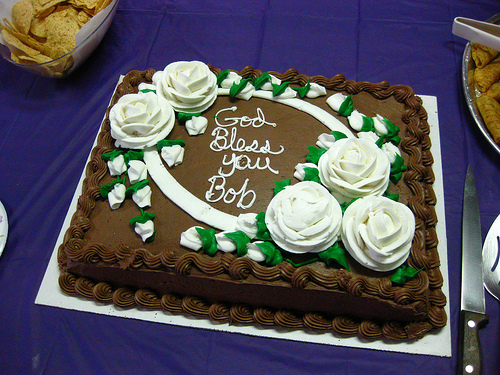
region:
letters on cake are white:
[196, 90, 286, 237]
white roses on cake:
[115, 50, 411, 342]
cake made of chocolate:
[76, 47, 430, 341]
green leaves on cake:
[101, 140, 389, 286]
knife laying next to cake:
[448, 158, 489, 371]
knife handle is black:
[444, 301, 494, 367]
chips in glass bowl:
[3, 0, 103, 70]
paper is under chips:
[1, 2, 101, 56]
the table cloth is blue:
[1, 0, 491, 359]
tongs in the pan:
[444, 8, 499, 58]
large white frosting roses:
[257, 129, 414, 279]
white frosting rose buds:
[99, 141, 282, 262]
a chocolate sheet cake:
[50, 54, 465, 341]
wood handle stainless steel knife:
[453, 148, 485, 374]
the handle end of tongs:
[448, 7, 498, 54]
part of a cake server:
[478, 171, 498, 359]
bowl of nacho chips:
[1, 6, 111, 82]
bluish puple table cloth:
[4, 69, 76, 372]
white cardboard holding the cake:
[28, 269, 295, 361]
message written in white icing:
[191, 99, 292, 214]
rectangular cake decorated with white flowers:
[55, 41, 457, 349]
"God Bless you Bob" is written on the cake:
[191, 95, 293, 216]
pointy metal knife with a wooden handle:
[449, 142, 499, 371]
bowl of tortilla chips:
[6, 5, 119, 71]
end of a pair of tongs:
[442, 6, 498, 63]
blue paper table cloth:
[166, 4, 427, 67]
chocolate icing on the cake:
[51, 220, 194, 342]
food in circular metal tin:
[449, 15, 499, 164]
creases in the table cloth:
[138, 0, 429, 68]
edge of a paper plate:
[1, 140, 16, 312]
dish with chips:
[0, 0, 115, 73]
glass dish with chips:
[0, 0, 117, 77]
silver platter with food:
[452, 11, 498, 153]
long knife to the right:
[458, 165, 487, 368]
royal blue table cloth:
[2, 0, 497, 373]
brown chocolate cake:
[57, 60, 446, 345]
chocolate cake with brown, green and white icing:
[55, 59, 448, 346]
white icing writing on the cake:
[205, 105, 283, 208]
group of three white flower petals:
[265, 133, 407, 269]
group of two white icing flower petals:
[105, 59, 221, 146]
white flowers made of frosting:
[251, 107, 448, 304]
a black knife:
[428, 142, 494, 372]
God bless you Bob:
[173, 76, 296, 227]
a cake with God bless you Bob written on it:
[96, 65, 452, 355]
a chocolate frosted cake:
[77, 70, 466, 342]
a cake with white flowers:
[76, 61, 451, 338]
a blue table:
[18, 85, 476, 368]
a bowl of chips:
[1, 1, 125, 71]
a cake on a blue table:
[52, 40, 498, 373]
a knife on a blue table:
[379, 131, 496, 363]